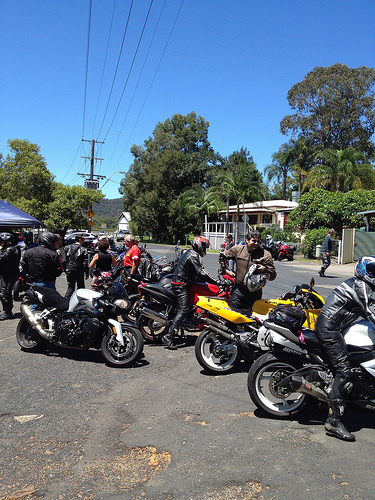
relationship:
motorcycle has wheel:
[20, 273, 145, 365] [103, 319, 156, 368]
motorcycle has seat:
[20, 273, 145, 365] [34, 277, 79, 311]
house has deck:
[215, 197, 311, 239] [201, 220, 230, 248]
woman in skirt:
[91, 239, 114, 293] [91, 275, 112, 292]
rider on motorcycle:
[175, 234, 196, 339] [20, 273, 145, 365]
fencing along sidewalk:
[341, 224, 367, 272] [295, 259, 322, 273]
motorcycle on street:
[20, 273, 145, 365] [54, 374, 235, 466]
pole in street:
[73, 125, 110, 198] [54, 374, 235, 466]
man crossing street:
[318, 227, 330, 279] [54, 374, 235, 466]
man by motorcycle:
[318, 227, 330, 279] [20, 273, 145, 365]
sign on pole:
[78, 206, 99, 218] [89, 137, 95, 182]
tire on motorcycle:
[198, 327, 245, 384] [20, 273, 145, 365]